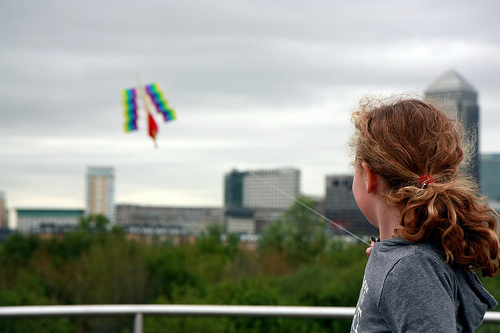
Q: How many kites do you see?
A: One.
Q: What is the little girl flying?
A: Kite.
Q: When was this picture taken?
A: Daytime.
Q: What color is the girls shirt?
A: Grey.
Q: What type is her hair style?
A: Ponytail.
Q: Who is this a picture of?
A: Girl.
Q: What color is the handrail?
A: White.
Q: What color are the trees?
A: Green.